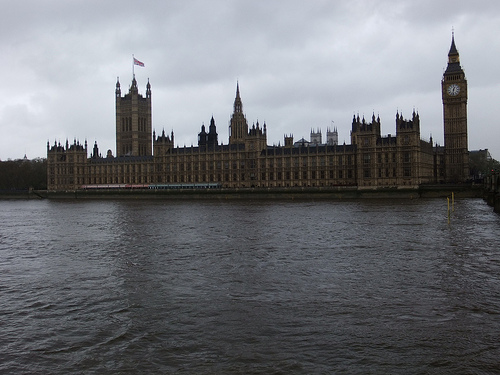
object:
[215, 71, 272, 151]
tower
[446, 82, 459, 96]
clock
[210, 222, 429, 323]
water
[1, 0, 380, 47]
clouds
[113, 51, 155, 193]
tower flag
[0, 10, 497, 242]
day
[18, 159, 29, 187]
foliage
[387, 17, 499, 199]
tower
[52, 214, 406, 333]
water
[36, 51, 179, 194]
castle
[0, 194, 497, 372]
water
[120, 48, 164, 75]
flag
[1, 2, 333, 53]
sky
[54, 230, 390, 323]
water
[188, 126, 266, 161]
wall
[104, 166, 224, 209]
photo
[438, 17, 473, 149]
tower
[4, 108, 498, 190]
building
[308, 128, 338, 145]
towers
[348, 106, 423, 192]
towers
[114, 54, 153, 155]
towers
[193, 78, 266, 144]
towers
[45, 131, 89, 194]
towers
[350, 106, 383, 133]
spires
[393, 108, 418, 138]
spires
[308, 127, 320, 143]
spires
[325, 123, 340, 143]
spires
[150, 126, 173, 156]
spires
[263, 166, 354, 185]
windows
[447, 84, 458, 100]
numbers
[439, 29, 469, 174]
tower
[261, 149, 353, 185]
windows